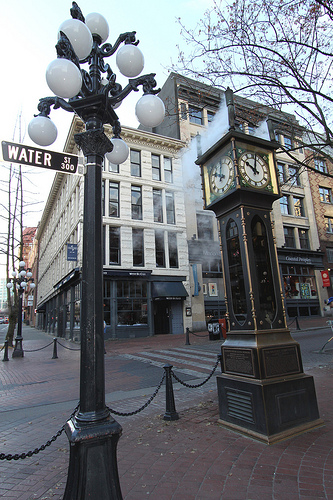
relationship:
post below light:
[75, 128, 111, 413] [26, 10, 167, 162]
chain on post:
[124, 389, 158, 408] [161, 363, 178, 421]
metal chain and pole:
[107, 380, 178, 424] [162, 360, 192, 430]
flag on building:
[65, 241, 80, 260] [39, 72, 329, 340]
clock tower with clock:
[195, 133, 295, 367] [238, 145, 282, 208]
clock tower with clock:
[195, 133, 295, 367] [205, 160, 240, 190]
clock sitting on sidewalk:
[237, 150, 267, 186] [124, 428, 275, 457]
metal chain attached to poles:
[107, 380, 178, 424] [152, 355, 191, 417]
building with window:
[37, 112, 191, 352] [128, 145, 142, 177]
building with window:
[37, 112, 191, 352] [149, 150, 161, 181]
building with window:
[37, 112, 191, 352] [163, 153, 174, 183]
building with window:
[37, 112, 191, 352] [107, 178, 120, 218]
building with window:
[37, 112, 191, 352] [129, 180, 144, 222]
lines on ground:
[240, 445, 273, 498] [0, 321, 332, 498]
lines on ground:
[191, 431, 241, 498] [0, 321, 332, 498]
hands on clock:
[213, 163, 227, 181] [210, 152, 233, 196]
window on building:
[150, 186, 163, 224] [126, 128, 184, 269]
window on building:
[162, 187, 173, 222] [126, 128, 184, 269]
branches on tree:
[20, 180, 40, 213] [4, 167, 51, 366]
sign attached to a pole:
[0, 142, 86, 175] [76, 146, 102, 386]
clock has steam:
[196, 136, 282, 212] [177, 90, 265, 280]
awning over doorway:
[153, 281, 189, 298] [149, 276, 186, 344]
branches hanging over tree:
[169, 0, 330, 181] [177, 1, 330, 145]